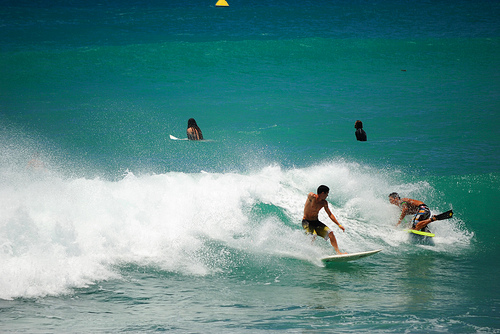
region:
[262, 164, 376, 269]
surfer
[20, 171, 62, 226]
white and green ocean wves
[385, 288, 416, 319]
white and green ocean wves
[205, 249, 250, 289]
white and green ocean wves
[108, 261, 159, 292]
white and green ocean wves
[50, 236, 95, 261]
white and green ocean wves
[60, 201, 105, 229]
white and green ocean wves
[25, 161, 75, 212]
white and green ocean wves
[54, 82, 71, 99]
white and green ocean wves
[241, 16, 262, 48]
white and green ocean wves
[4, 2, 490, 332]
a scene outside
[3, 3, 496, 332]
a scene during the day time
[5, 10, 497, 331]
a photo at the ocean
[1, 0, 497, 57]
a blue portion of water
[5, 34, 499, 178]
a green portion of water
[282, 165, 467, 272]
some surfers in the water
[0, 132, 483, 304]
a white wave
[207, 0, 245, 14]
a yellow object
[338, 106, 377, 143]
a person in the water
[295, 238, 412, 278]
a white surfboard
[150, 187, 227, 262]
th white water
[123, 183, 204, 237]
a wave in the water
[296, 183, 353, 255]
a man surfing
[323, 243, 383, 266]
a surfboard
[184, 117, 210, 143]
a person in the water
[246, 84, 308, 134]
the water is green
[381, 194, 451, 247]
a person in the water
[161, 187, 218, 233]
the water is white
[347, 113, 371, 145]
a man in the water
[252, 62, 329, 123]
the oceans water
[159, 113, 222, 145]
woman in water on surfboard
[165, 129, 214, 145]
white surfboard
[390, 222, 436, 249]
green yellow surfboard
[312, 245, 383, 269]
top of white surfboard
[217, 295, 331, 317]
dark line ripples in water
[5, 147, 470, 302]
large water wave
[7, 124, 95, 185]
white water splash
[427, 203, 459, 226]
black water flipper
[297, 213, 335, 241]
black and gold shorts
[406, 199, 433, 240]
multi-color shorts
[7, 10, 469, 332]
a scene during the day time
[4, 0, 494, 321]
a photo of a ocean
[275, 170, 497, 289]
a couple of surfers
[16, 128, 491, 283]
a white wave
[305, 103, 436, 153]
a person in the water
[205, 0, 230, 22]
a yellow object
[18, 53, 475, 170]
a green portion of water